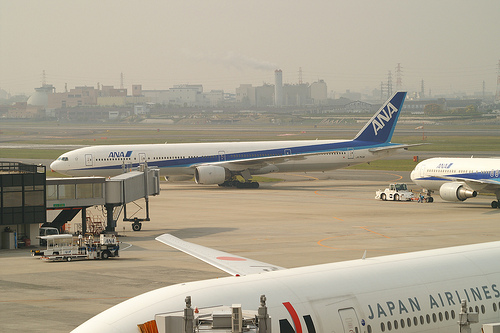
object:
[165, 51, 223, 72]
grey sky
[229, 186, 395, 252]
clear ground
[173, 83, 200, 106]
brick building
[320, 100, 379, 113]
big bridge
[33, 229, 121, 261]
business truck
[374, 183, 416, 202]
toad truck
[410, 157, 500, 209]
plane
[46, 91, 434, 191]
plane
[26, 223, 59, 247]
truck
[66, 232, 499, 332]
plane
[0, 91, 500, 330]
airport scene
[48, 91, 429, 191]
passenger jet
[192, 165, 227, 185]
jet's engines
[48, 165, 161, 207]
boarding gate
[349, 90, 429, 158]
tail section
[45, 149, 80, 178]
nose section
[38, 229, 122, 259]
hauling vehicle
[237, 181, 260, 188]
landing gears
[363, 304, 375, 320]
letters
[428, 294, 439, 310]
letters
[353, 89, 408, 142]
tail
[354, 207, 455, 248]
concrete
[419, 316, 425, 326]
windows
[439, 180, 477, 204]
engine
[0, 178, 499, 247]
platform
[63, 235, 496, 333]
airplane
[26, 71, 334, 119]
city